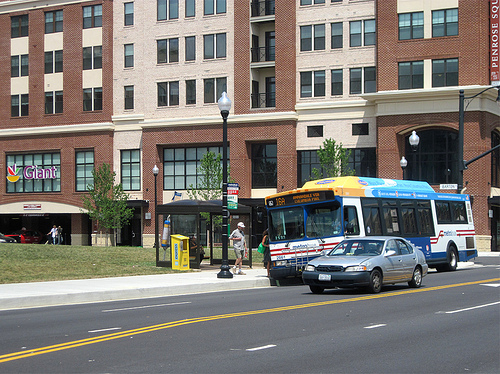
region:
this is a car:
[318, 243, 410, 280]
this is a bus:
[316, 182, 463, 239]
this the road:
[213, 290, 309, 370]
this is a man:
[231, 220, 257, 272]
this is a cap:
[236, 220, 248, 225]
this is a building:
[49, 13, 223, 121]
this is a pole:
[453, 90, 469, 185]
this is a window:
[314, 25, 326, 47]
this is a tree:
[91, 171, 131, 234]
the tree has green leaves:
[101, 184, 117, 201]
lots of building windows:
[11, 0, 483, 117]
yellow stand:
[171, 234, 190, 271]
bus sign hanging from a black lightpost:
[216, 90, 238, 275]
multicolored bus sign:
[225, 183, 239, 208]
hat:
[234, 220, 247, 228]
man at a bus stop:
[158, 181, 251, 278]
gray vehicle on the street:
[296, 231, 442, 291]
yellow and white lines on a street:
[6, 280, 497, 363]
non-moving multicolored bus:
[263, 175, 489, 280]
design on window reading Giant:
[6, 155, 62, 191]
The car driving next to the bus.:
[302, 235, 425, 289]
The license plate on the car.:
[314, 269, 333, 281]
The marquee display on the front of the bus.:
[264, 187, 326, 206]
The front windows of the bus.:
[269, 205, 346, 239]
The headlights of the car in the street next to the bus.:
[302, 260, 369, 277]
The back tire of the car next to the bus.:
[412, 264, 425, 287]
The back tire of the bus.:
[441, 244, 461, 266]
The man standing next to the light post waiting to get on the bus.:
[228, 212, 250, 275]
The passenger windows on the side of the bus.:
[361, 201, 471, 238]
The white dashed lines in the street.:
[72, 300, 497, 341]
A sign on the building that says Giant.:
[2, 146, 72, 203]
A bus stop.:
[143, 187, 263, 282]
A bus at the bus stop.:
[256, 167, 484, 297]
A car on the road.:
[292, 231, 453, 304]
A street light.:
[206, 77, 248, 282]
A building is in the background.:
[3, 0, 495, 263]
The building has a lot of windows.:
[6, 2, 468, 162]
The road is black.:
[388, 330, 495, 364]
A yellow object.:
[162, 222, 196, 277]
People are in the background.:
[23, 211, 82, 246]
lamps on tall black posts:
[140, 74, 445, 281]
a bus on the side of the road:
[255, 161, 486, 291]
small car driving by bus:
[275, 198, 427, 300]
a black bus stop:
[149, 188, 256, 278]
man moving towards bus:
[216, 165, 329, 290]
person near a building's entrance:
[1, 194, 101, 249]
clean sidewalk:
[0, 258, 268, 310]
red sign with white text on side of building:
[460, 1, 498, 93]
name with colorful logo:
[1, 143, 62, 197]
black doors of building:
[105, 193, 150, 253]